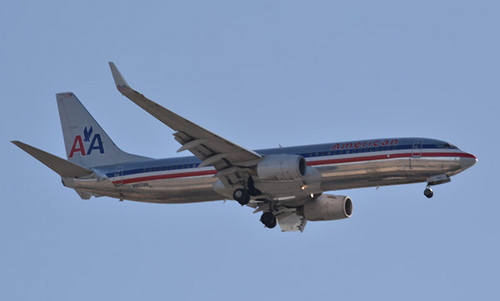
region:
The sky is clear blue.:
[3, 0, 498, 99]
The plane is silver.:
[0, 58, 490, 238]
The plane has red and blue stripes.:
[11, 60, 496, 244]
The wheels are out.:
[226, 180, 292, 231]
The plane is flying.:
[28, 73, 497, 240]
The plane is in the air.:
[28, 65, 492, 238]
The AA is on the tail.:
[60, 125, 117, 165]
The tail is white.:
[15, 84, 140, 184]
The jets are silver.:
[260, 145, 360, 226]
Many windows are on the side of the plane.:
[108, 139, 432, 173]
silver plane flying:
[18, 83, 486, 226]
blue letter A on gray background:
[85, 130, 105, 155]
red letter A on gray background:
[67, 134, 84, 160]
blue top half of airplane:
[93, 128, 465, 178]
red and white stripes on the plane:
[107, 138, 472, 188]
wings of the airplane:
[8, 49, 255, 210]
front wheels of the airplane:
[415, 182, 439, 199]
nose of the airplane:
[463, 147, 479, 168]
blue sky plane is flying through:
[2, 7, 494, 297]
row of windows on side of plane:
[113, 133, 401, 185]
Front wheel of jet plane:
[416, 177, 444, 207]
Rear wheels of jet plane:
[227, 179, 290, 242]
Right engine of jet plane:
[247, 143, 319, 196]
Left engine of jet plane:
[296, 184, 361, 233]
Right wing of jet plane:
[92, 57, 269, 189]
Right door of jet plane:
[404, 137, 429, 169]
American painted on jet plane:
[326, 134, 412, 154]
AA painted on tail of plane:
[59, 118, 114, 165]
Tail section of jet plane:
[10, 80, 125, 204]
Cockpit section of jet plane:
[438, 133, 481, 190]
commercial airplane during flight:
[10, 58, 477, 231]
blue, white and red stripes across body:
[95, 141, 477, 183]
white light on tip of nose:
[471, 150, 476, 165]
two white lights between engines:
[296, 181, 312, 196]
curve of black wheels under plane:
[230, 180, 276, 226]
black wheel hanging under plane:
[420, 171, 432, 196]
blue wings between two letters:
[65, 120, 105, 155]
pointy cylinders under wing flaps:
[175, 130, 240, 180]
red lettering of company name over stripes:
[328, 135, 398, 157]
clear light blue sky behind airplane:
[1, 5, 496, 295]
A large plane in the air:
[24, 73, 474, 228]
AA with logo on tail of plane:
[66, 113, 111, 163]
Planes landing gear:
[226, 178, 281, 245]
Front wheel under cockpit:
[422, 176, 434, 203]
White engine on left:
[253, 151, 308, 185]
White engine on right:
[308, 196, 354, 226]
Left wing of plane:
[107, 65, 252, 166]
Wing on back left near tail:
[11, 135, 86, 185]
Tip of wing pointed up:
[101, 51, 132, 91]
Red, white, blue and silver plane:
[315, 135, 437, 183]